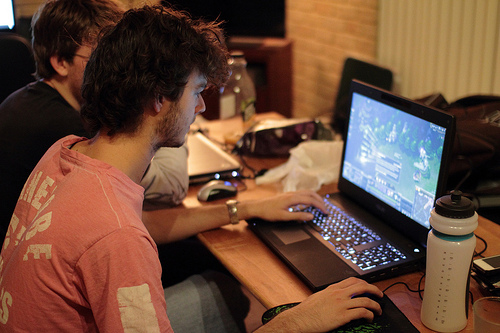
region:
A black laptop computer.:
[247, 79, 457, 315]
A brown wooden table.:
[137, 110, 497, 329]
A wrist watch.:
[225, 194, 242, 226]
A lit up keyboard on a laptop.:
[289, 192, 408, 279]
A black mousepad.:
[259, 285, 421, 331]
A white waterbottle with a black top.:
[423, 187, 482, 332]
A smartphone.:
[472, 252, 498, 279]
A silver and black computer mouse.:
[194, 179, 242, 202]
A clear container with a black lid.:
[218, 49, 256, 146]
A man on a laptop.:
[20, 2, 466, 331]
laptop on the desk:
[275, 82, 456, 303]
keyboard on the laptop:
[314, 208, 376, 268]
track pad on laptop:
[273, 226, 308, 253]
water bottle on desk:
[426, 188, 467, 330]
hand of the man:
[263, 187, 319, 230]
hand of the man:
[318, 268, 373, 328]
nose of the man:
[190, 100, 209, 119]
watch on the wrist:
[223, 197, 248, 226]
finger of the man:
[356, 308, 378, 324]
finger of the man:
[360, 294, 388, 307]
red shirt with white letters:
[6, 185, 143, 291]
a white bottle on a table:
[421, 173, 479, 331]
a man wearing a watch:
[208, 187, 258, 237]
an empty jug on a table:
[222, 48, 274, 157]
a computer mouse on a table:
[183, 168, 263, 210]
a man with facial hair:
[146, 90, 204, 161]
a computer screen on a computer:
[343, 91, 455, 240]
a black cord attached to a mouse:
[370, 268, 466, 315]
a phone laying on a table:
[463, 245, 498, 285]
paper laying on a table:
[273, 140, 344, 194]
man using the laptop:
[14, 20, 494, 332]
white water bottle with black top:
[418, 188, 492, 326]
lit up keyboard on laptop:
[302, 193, 394, 270]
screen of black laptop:
[349, 93, 443, 215]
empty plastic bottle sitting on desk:
[212, 53, 264, 141]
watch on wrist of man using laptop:
[225, 194, 240, 217]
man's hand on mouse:
[288, 279, 385, 329]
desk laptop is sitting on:
[171, 106, 484, 332]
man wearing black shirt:
[9, 14, 188, 241]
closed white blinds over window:
[377, 5, 494, 96]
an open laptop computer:
[243, 80, 456, 300]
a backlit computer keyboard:
[291, 194, 408, 273]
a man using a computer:
[8, 9, 455, 329]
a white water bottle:
[420, 187, 482, 331]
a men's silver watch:
[223, 197, 241, 227]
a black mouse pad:
[264, 286, 417, 331]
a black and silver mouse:
[194, 176, 238, 206]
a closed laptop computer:
[186, 129, 243, 189]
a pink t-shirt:
[3, 132, 173, 330]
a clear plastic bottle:
[219, 50, 256, 148]